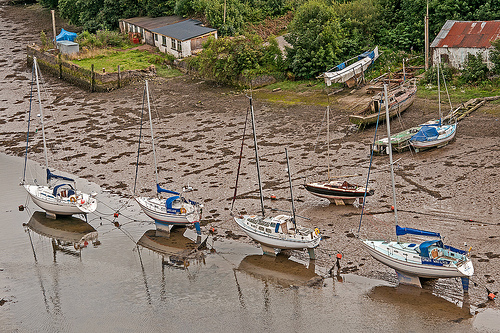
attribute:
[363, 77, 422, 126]
boat — wooden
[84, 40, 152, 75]
grass — green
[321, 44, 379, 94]
boat — white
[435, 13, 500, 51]
roof — rusted, flat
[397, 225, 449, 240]
mast — rolled up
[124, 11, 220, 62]
shed — white